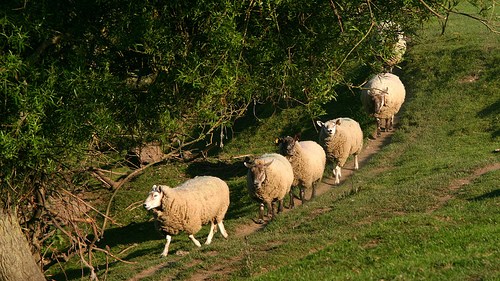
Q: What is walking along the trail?
A: Sheep.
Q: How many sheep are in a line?
A: 6.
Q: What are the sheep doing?
A: Walking in a line.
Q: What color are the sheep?
A: Tan.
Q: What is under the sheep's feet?
A: A trail.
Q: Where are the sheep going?
A: Downhill.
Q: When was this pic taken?
A: During the day.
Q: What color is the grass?
A: Green.